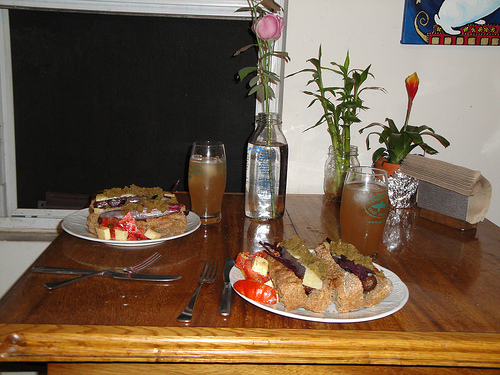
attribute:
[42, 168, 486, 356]
wood table — brown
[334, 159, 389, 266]
beverage — iced tea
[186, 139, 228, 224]
glass —  of iced tea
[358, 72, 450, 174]
potted flower —  potted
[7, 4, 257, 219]
window — open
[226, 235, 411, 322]
meal — set,  for two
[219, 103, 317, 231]
vase — drink bottle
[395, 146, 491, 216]
napkins — brown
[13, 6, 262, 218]
screen — closed